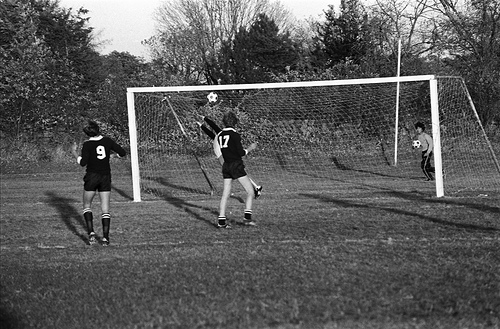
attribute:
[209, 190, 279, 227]
socks — long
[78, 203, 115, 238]
socks — long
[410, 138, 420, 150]
ball — for volley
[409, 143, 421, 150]
hand —  boy's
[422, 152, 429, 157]
hand —  boy's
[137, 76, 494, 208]
net —  soccer's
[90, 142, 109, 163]
9 — number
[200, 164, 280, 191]
shorts — black 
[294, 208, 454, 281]
grass —  ground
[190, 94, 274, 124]
soccer ball — for soccer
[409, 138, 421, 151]
ball — black, white, soccer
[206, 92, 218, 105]
ball — black, white, soccer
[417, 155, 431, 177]
pants — black 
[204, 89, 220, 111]
soccer ball — for soccer,  in air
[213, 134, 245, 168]
shirt — beige 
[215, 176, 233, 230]
leg —  person's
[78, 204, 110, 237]
socks — black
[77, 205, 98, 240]
sock — tall , black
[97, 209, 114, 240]
sock — tall , black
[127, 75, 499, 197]
net — Large 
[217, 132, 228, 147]
number — 17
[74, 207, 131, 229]
socks — navy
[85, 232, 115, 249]
sneakers — black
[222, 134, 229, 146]
number — seven 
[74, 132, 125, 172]
shirt — long-sleeve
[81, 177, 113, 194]
shorts — Black 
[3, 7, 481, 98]
sky — clear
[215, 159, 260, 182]
shorts — black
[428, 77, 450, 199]
pole — white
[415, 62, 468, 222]
pole — metal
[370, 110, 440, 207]
child — for soccer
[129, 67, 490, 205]
net — soccer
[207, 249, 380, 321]
grass —  green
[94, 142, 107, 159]
nine —  number